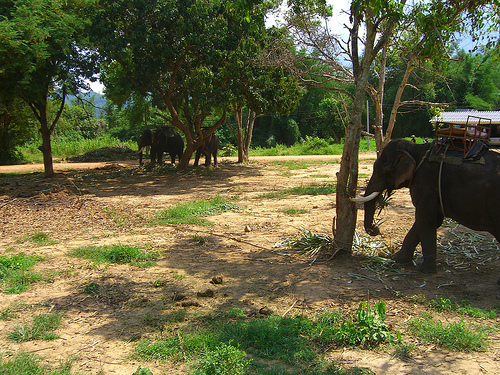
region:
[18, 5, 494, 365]
elephants under shade of trees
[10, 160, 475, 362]
dried brown dirt with grassy patches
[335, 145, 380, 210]
curved tusks curling toward tree trunk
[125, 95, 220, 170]
elephants on different sides of slanted tree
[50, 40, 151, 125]
mountain and bright sky through trees and bushes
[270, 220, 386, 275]
narrow leaves around base of tree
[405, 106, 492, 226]
empty bench on top of elephant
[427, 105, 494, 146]
low building with gray roof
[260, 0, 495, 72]
clouds and blue sky through trees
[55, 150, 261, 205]
dappled shade under elephant's feet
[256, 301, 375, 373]
green grass on the ground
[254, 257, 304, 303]
brown dirt on the ground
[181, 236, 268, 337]
shadow on the ground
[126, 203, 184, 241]
light hitting the ground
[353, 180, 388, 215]
tusk of the elephant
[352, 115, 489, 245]
elephant on the ground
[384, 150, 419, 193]
ear of the elephant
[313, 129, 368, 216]
tree next to elephant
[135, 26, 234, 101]
leaves on the tree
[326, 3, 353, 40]
sky above the trees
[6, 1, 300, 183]
elephants in trees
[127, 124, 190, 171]
single elephant with tusks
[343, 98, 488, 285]
elephant used to move things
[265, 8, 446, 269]
tree and elephant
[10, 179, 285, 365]
sand and grass prarie in Africa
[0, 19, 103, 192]
tree in sandy area in Africa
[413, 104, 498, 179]
African elephant saddle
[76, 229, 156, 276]
patch of green grass in prarie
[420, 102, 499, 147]
modern barn with metal roof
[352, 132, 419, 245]
head of elephant with tusks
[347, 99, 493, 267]
elephant with seat on his back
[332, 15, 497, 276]
elephant standing by tree in foreground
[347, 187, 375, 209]
white tusk of elephant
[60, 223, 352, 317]
shadow of tree on ground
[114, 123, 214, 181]
two elephants standing under tree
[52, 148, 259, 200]
shadow of trees in background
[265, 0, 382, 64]
cloud behind tree branches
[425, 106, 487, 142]
seat on top of elephant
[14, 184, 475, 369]
patches of grass in dirt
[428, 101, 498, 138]
building behind elephant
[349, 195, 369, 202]
A tusk against a tree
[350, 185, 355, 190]
A tusk scratch mark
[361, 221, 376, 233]
A coiled elephant trunk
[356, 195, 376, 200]
An elephant tusk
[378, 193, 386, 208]
Palm leaves in the mouth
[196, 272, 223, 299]
Elephant droppings on the ground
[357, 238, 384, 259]
Palm leaves on the ground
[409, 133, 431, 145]
Two people in the background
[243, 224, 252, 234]
A piece of rock on the ground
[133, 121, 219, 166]
Two elephants under a tree